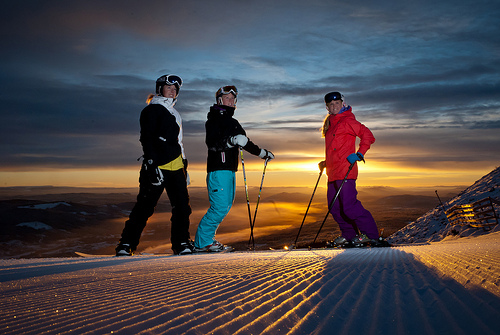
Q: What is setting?
A: The sun.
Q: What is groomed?
A: The snow.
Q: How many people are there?
A: Three.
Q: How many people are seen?
A: Three.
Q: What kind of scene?
A: Sunset.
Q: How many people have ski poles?
A: Two.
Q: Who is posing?
A: A skier.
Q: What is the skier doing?
A: Posing for a picture.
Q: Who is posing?
A: Snowboarder.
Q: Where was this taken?
A: Ski slope.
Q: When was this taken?
A: Winter.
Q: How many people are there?
A: 3.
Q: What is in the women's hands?
A: Ski poles.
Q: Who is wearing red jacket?
A: Female skier.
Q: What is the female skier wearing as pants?
A: Purple ski pants.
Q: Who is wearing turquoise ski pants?
A: The female skier.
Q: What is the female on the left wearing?
A: Black skiing outfit.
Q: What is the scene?
A: Sunrise at a ski slope and skiers.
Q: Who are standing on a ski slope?
A: Female skiers.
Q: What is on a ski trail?
A: Grooming grooves.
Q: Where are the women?
A: On the side of a mountain.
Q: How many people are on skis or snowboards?
A: Three people.